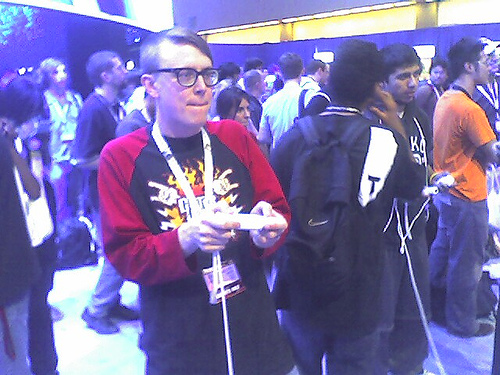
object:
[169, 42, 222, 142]
face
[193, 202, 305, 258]
video game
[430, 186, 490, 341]
gray pants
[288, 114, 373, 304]
backpack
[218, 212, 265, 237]
wii controller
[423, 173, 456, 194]
wii controller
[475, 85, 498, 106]
landyard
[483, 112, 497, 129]
name tag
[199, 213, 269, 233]
controller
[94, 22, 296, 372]
he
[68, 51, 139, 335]
man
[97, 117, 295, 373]
t-shirt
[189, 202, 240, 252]
hand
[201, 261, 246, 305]
name badge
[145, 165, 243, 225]
logo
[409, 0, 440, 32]
light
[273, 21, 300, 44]
light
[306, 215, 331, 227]
logo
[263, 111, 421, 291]
shirt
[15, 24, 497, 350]
crowd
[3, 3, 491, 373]
room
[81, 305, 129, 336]
shoe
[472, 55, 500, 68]
eyeglasses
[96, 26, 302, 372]
man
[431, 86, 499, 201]
orange t-shirt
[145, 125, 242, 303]
lanyard/name tag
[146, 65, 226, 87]
eye glasses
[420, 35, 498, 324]
man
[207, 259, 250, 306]
tag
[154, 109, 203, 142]
neck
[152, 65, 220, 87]
frame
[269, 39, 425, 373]
man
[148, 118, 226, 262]
lanyard